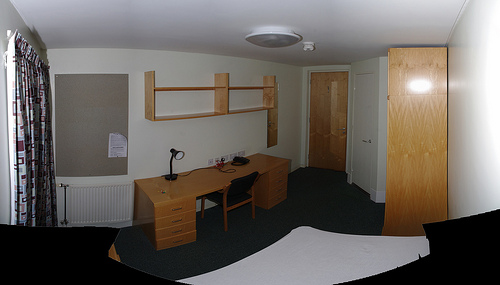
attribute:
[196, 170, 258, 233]
chair — black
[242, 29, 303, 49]
light — off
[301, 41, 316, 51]
fire alarm — white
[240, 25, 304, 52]
ceiling light — round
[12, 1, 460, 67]
ceiling — white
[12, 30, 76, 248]
curtain — grey, red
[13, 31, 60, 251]
curtains — floor length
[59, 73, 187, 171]
board — cork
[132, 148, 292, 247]
desk — tan, wooden, wood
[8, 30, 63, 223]
curtains — long, blue, purple, pink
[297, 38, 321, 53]
fire alarm — white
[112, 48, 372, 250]
wall — white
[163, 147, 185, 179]
lamp — black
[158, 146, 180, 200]
lamp — black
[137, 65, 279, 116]
book shelf — light wooden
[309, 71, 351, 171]
wooden door — brown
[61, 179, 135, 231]
radiator — white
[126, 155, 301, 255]
desk — brown, wooden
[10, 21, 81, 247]
curtains — closed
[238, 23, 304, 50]
light — white